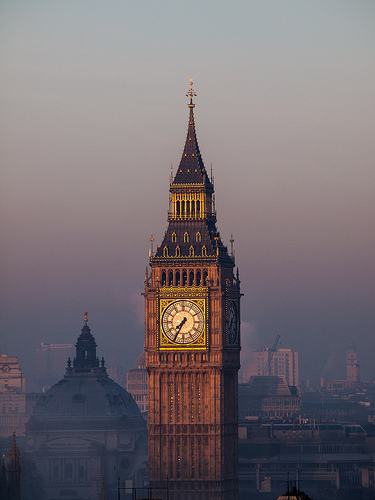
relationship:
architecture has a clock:
[141, 78, 245, 499] [156, 288, 209, 351]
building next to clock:
[30, 335, 141, 472] [155, 286, 206, 347]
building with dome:
[344, 340, 359, 399] [345, 341, 355, 350]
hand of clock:
[173, 320, 181, 337] [162, 298, 202, 345]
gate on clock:
[110, 480, 171, 497] [156, 297, 209, 345]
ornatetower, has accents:
[141, 78, 245, 498] [170, 190, 205, 217]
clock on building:
[1, 364, 11, 372] [1, 350, 25, 412]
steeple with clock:
[165, 77, 216, 220] [159, 295, 206, 346]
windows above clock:
[158, 265, 209, 288] [159, 295, 206, 346]